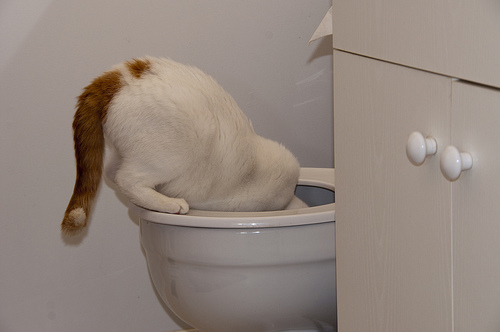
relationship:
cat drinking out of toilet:
[53, 54, 302, 247] [138, 164, 339, 328]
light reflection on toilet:
[235, 219, 260, 235] [138, 203, 379, 329]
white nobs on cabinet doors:
[404, 130, 474, 180] [333, 51, 499, 316]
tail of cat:
[55, 64, 124, 244] [53, 54, 302, 247]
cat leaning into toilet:
[53, 54, 312, 233] [138, 164, 339, 328]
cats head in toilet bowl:
[288, 192, 312, 212] [125, 192, 310, 329]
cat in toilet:
[53, 54, 312, 233] [138, 164, 339, 328]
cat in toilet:
[53, 54, 302, 247] [138, 164, 339, 328]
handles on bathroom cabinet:
[402, 126, 472, 185] [332, 0, 498, 331]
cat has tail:
[53, 54, 312, 233] [62, 71, 122, 234]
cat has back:
[53, 54, 302, 247] [120, 44, 275, 130]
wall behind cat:
[3, 4, 333, 330] [53, 54, 312, 233]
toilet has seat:
[138, 164, 339, 328] [128, 180, 375, 228]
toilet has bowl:
[138, 164, 339, 332] [121, 155, 348, 330]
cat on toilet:
[53, 54, 302, 247] [108, 150, 356, 330]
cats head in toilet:
[288, 197, 312, 212] [138, 164, 339, 328]